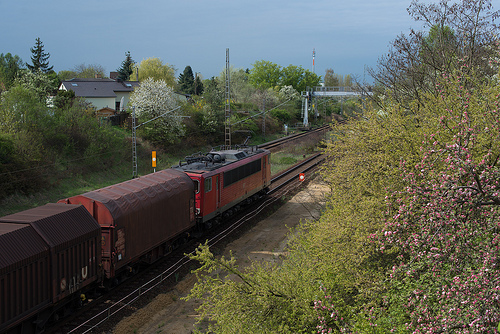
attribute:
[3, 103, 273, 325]
train — old, moving, rusty, Three train , red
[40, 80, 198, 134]
neighborhood — residential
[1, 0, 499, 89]
sky — clear, blue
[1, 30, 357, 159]
trees — green, blooming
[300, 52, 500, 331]
leaves — colorful, pink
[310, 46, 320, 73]
tower — small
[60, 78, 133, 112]
house — white, partially hidden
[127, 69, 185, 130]
tree — white, tall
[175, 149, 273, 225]
caboose — red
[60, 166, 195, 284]
train car — red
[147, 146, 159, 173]
train sign — orange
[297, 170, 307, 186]
train sign — red